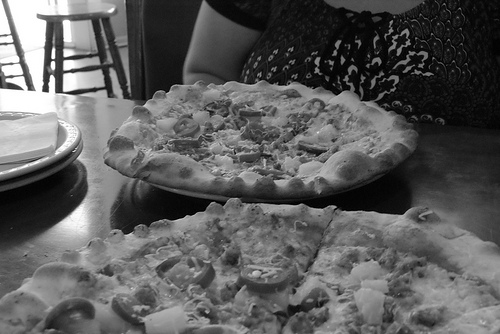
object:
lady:
[180, 0, 500, 129]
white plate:
[0, 110, 84, 192]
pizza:
[0, 197, 500, 334]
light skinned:
[181, 0, 263, 86]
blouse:
[201, 0, 500, 130]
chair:
[36, 0, 131, 100]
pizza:
[102, 79, 419, 199]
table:
[0, 80, 500, 334]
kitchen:
[0, 0, 500, 334]